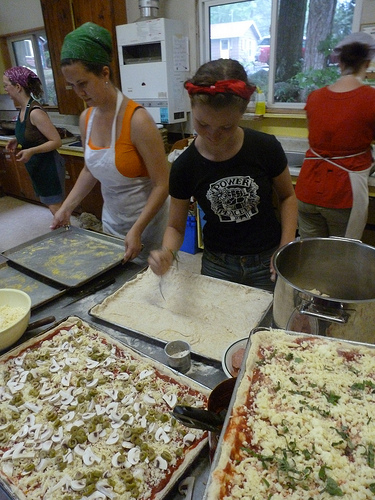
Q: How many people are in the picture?
A: Four.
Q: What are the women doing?
A: They are cooking.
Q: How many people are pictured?
A: Four.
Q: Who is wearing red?
A: Person on right.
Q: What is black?
A: A girl's shirt.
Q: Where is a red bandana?
A: In a girl's hair.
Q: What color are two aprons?
A: White.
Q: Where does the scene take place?
A: In a kitchen.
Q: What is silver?
A: A pot.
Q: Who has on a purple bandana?
A: Woman on left.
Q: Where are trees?
A: Outside the window.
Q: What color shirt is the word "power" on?
A: Black.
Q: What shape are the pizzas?
A: Square.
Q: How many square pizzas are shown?
A: Two.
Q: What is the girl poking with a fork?
A: Crust.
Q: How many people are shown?
A: Four.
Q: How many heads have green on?
A: One.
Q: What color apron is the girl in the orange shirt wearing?
A: White.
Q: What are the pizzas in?
A: Metal pans.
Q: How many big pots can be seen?
A: One.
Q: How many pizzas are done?
A: 2.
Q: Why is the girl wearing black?
A: Fashion.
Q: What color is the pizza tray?
A: Silver.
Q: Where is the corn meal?
A: On tray.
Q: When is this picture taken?
A: During day.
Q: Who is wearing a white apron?
A: Woman in orange.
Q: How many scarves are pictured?
A: 4.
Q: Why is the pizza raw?
A: Not baked.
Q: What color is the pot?
A: Stainless steel.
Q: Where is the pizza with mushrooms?
A: On table.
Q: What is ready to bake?
A: The rectangular pizza.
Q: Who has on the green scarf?
A: The woman holding the dirty tray.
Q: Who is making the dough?
A: Woman in black shirt.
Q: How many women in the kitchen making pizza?
A: Four.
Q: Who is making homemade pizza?
A: The women.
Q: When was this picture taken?
A: Daytime.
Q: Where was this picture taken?
A: In the kitchen.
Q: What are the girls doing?
A: Making pizza.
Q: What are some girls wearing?
A: Aprons.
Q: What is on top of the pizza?
A: Cheese.